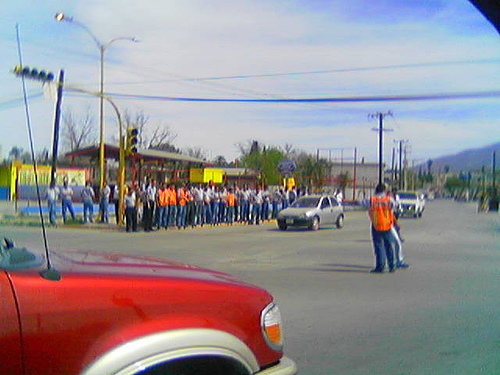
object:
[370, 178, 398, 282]
man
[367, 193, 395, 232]
vest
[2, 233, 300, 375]
suv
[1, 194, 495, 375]
street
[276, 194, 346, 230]
car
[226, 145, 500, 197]
trees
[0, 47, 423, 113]
powerlines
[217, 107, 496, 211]
distance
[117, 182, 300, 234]
people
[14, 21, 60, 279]
attenna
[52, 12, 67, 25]
headlight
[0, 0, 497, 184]
sky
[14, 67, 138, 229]
traffic signal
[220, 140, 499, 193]
leaves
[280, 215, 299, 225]
license plate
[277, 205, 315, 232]
front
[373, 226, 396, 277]
jeans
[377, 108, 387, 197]
pole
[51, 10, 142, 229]
pole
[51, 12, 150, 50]
light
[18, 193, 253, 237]
side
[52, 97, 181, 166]
tree